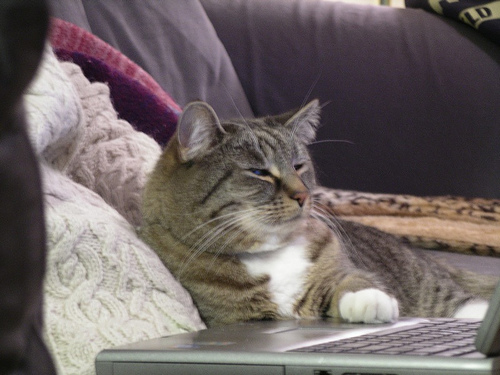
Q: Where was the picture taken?
A: In a living room.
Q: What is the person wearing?
A: A sweater.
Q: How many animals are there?
A: One.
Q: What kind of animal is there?
A: A cat.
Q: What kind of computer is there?
A: A laptop.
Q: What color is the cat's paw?
A: White.